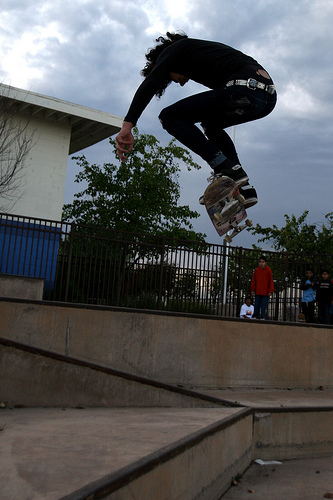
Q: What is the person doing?
A: A skateboard trick.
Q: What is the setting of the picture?
A: A skateboard park.